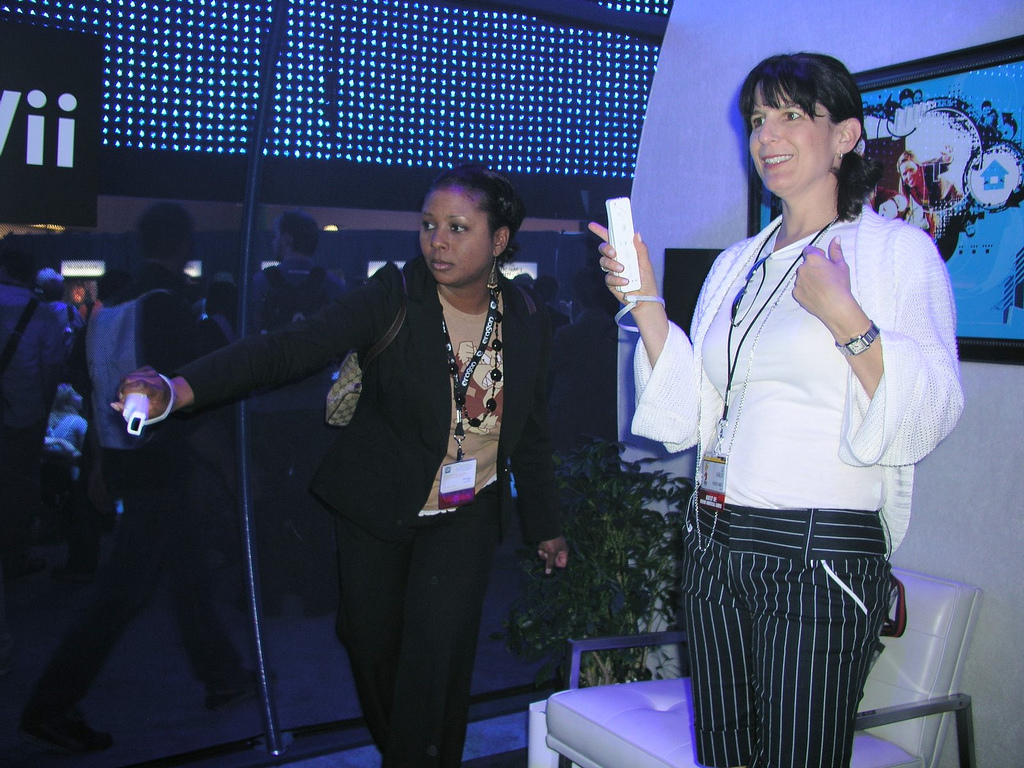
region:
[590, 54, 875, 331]
a woman holding a Wii remote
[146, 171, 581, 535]
a woman wearing a black suit jacket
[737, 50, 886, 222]
a woman with black hair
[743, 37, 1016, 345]
framed artwork on the wall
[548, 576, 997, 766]
a white chair with metal armrests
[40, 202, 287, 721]
a man that is walking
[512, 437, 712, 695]
the foliage of a green plant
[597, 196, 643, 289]
handle inside of hand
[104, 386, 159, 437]
game remote inside hand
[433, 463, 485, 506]
badge around the neck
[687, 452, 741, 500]
badge around the neck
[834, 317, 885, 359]
watch around the woman's wrist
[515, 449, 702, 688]
plant in the corner of room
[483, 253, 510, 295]
earring attached to woman's ear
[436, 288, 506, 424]
necklace around woman's neck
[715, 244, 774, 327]
sunglasses on top of woman's shirt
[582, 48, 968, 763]
woman holding wii remote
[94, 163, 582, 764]
woman holding wii remote in right hand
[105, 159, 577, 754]
woman wearing black suit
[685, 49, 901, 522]
name tag around womans neck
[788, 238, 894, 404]
silver watch on left hand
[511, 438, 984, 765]
green plant beside white chair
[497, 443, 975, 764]
white chair beside green plant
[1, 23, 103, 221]
black and white wii sign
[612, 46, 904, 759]
woman smiling holding wii remote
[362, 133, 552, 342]
face of the girl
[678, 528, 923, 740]
pants of the girl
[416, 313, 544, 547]
a id card wearing by girl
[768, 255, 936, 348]
hand of the girl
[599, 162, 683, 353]
a remote holding by girl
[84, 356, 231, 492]
band tied to hand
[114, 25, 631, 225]
a view of wall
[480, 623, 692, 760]
a view of chair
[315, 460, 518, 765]
Woman wearing pants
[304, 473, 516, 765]
Woman is wearing pants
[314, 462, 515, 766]
Woman wearing black pants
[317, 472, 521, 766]
Woman is wearing black pants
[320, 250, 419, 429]
Woman carrying a purse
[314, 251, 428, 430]
Woman is carrying a purse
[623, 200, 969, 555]
Woman wearing a white shirt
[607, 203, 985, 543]
Woman is wearing a white shirt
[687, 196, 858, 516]
Woman is wearing a lanyard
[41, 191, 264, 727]
A person is standing up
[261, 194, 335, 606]
A person is standing up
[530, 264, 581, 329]
A person is standing up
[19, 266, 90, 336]
A person is standing up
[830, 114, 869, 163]
Ear of a woman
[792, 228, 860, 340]
Hand of a woman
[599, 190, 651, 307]
Wii controller in a hand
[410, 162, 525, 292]
Head of a woman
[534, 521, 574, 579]
Hand of a woman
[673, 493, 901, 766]
Pants on a woman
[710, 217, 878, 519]
Shirt on a woman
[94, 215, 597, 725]
The woman to the left holding the controller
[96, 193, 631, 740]
A woman to the left holding the controller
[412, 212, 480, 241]
The eyes of the left woman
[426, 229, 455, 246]
A nose on the left woman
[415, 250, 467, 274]
The mouth on the left woman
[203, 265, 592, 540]
A black jacket on the woman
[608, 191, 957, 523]
lady in white shirt